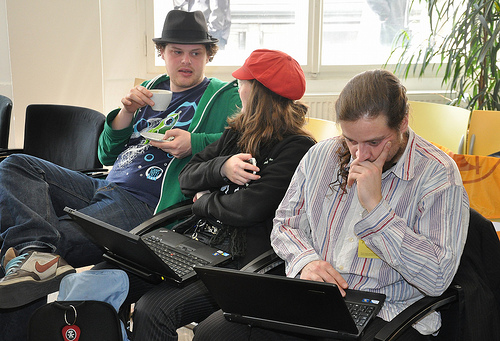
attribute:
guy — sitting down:
[120, 28, 204, 207]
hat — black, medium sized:
[159, 13, 219, 45]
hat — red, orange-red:
[237, 34, 309, 104]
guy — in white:
[312, 85, 445, 309]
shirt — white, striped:
[310, 137, 444, 286]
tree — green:
[439, 10, 491, 72]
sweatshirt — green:
[178, 76, 248, 177]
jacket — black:
[264, 133, 299, 192]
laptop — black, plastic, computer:
[94, 204, 216, 269]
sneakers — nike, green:
[3, 253, 76, 299]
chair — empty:
[19, 98, 102, 157]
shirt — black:
[211, 146, 271, 245]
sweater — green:
[181, 80, 221, 168]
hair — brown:
[334, 69, 409, 117]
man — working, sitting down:
[323, 39, 447, 285]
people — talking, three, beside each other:
[130, 15, 296, 231]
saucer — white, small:
[137, 126, 172, 146]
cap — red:
[250, 39, 290, 100]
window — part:
[155, 6, 477, 65]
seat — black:
[21, 104, 104, 170]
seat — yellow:
[410, 110, 470, 152]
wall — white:
[6, 5, 103, 114]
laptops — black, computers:
[75, 205, 355, 299]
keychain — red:
[65, 299, 80, 338]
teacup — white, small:
[154, 95, 175, 121]